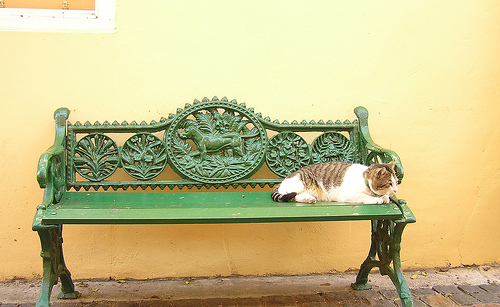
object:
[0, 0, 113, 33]
window sill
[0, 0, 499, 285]
wall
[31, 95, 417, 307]
bench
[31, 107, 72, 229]
armrest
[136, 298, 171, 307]
brick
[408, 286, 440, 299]
brick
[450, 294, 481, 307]
brick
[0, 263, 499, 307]
sidewalk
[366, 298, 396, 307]
brick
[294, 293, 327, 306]
brick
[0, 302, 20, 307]
brick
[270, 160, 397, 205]
cat